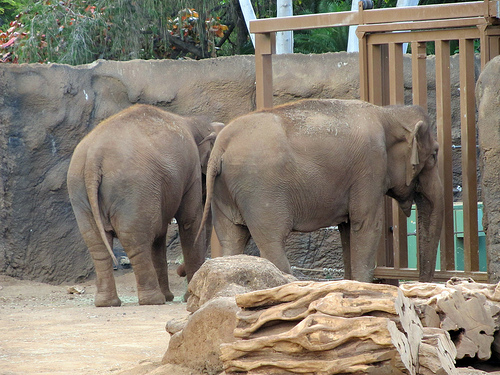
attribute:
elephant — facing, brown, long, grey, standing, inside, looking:
[168, 52, 441, 296]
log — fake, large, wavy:
[252, 283, 409, 360]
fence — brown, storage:
[322, 52, 477, 302]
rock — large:
[152, 229, 281, 339]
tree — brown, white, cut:
[163, 15, 229, 63]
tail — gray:
[195, 192, 230, 236]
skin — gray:
[309, 103, 360, 159]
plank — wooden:
[269, 294, 376, 348]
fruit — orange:
[212, 17, 236, 41]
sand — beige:
[41, 319, 124, 373]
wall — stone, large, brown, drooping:
[22, 117, 83, 183]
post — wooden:
[453, 55, 473, 264]